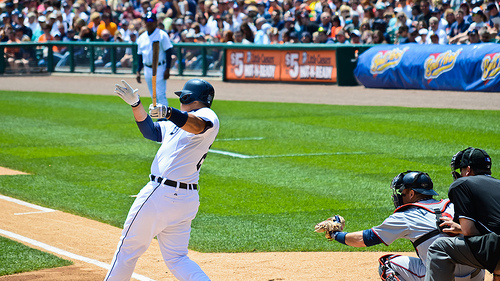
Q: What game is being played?
A: Baseball.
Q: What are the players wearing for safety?
A: Helmet.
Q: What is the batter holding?
A: A bat.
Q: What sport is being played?
A: Baseball.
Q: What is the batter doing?
A: Swinging.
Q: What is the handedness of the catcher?
A: Right handed.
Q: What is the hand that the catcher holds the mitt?
A: Left hand.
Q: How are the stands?
A: Filled with fans.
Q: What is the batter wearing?
A: White shirt and pants.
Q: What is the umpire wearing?
A: Black shirt and grey pants.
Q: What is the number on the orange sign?
A: 5.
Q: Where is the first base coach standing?
A: Outside the coach's box.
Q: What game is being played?
A: Baseball.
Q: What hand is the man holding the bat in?
A: Left.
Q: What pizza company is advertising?
A: Little Caesar's.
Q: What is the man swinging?
A: A bat.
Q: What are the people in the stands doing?
A: Watching the game.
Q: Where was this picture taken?
A: A baseball stadium.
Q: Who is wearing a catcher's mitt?
A: The catcher.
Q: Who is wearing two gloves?
A: The batter.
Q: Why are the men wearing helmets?
A: Protection.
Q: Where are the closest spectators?
A: Behind fence.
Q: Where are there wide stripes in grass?
A: Right of first base line.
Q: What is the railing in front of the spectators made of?
A: Metal.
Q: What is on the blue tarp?
A: Logos.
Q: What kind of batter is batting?
A: Right handed.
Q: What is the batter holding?
A: Baseball bat.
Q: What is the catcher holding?
A: Catchers mitt.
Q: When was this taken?
A: Daytime.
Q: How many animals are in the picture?
A: 0.